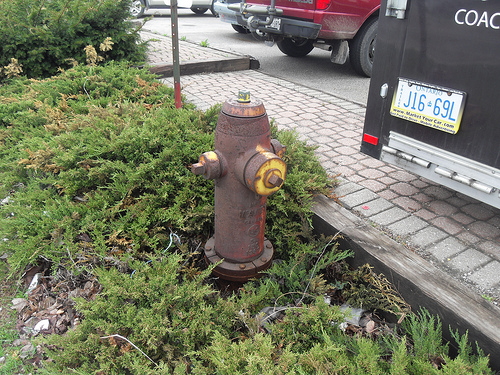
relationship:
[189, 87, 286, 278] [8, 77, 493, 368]
hydrant on ground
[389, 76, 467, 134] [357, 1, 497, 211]
license plate on car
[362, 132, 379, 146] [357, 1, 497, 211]
brake light on car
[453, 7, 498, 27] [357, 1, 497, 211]
letters on car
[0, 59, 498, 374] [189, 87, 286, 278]
bushes around hydrant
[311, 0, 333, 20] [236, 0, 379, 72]
tail light on truck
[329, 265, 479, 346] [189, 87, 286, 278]
log in front of hydrant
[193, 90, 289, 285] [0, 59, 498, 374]
hydrant in bushes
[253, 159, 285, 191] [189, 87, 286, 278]
cap on hydrant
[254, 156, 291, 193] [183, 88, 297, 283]
yellow paint on hydrant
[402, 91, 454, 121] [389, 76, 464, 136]
letters on plate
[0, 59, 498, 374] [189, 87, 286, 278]
bushes by hydrant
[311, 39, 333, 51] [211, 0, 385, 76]
exhaust under truck